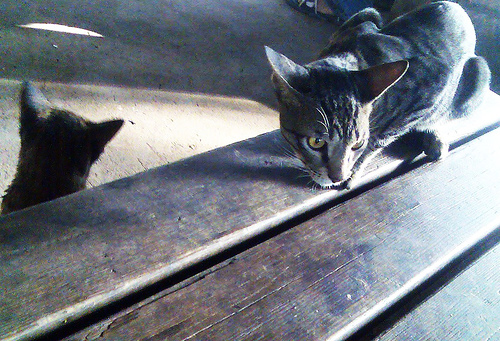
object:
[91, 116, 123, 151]
ear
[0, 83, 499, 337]
wood slates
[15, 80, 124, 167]
head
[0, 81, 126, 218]
cat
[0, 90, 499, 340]
bench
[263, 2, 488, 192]
hair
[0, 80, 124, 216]
hair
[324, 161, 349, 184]
nose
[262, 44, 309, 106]
ear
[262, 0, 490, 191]
cat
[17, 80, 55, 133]
ear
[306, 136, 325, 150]
eye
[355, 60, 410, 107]
ear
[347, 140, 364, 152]
eye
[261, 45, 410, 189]
head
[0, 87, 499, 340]
table top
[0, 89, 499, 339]
table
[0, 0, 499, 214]
floor